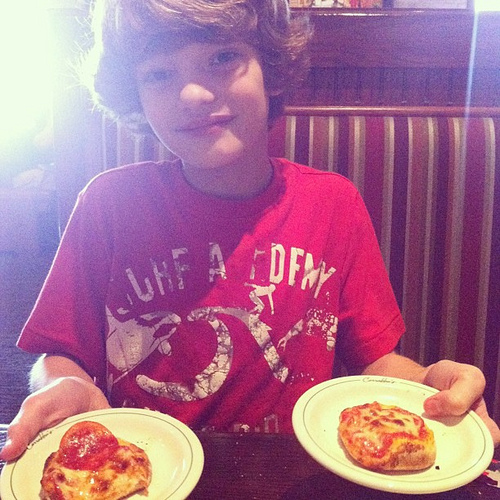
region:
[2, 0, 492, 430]
Young boy holding two saucers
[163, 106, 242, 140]
Mouth of little boy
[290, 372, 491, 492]
White saucer with gold circle near edge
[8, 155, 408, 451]
Red tee shirt with white writing on it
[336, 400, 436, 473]
Sweet roll sitting on white saucer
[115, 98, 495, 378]
Striped colored back of booth back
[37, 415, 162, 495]
Sweet roll with fruit on top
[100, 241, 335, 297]
White writing on red shirt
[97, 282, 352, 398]
White design on front of red shirt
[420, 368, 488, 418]
Left thumb of little boy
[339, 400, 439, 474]
a mini cheese pizza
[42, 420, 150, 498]
a mini pepperoni pizza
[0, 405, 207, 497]
a small white bowl plate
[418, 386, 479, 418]
a boy's thumb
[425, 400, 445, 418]
a boys thumb nail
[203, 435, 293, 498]
a section of brown table with crumbs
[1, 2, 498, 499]
a young boy holding two mini pizzas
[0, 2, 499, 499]
a young boy posing for a picture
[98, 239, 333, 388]
a picture of a shark and a surfer on a wave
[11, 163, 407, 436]
a young boys red shirt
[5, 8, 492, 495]
A kid is holding two plates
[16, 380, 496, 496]
Two plates of pizza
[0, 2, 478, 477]
Boy has on a red shirt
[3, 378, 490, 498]
The plates are plain white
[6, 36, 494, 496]
The boy is sitting in a booth in a food place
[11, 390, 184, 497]
Pepperoni pizza is on one plate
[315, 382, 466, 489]
Cheese pizza is in another plate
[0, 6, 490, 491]
The boy's red shirt has words on it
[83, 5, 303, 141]
A lot of hair on the boy's head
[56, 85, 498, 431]
The seat is striped with different colors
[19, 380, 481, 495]
two plates with pizza on them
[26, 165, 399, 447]
red shirt with white print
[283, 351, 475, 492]
white plate with cheese pizza on it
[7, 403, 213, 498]
white plate with pepperoni pizza on it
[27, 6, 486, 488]
boy holding two slices of pizza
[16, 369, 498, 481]
two white plates with dark colored ring on them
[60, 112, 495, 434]
booth child is sitting in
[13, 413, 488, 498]
table boy is sitting at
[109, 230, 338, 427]
white writing on red shirt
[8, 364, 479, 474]
hands holding white plates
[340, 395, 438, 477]
a mini personal cheese pizza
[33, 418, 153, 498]
a mini personal pepperoni pizza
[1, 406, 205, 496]
a small white shallow bowl with a stripe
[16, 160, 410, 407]
a child's red shirt with a picture of a shark and surfer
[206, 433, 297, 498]
part of a dark wooden table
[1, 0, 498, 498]
a young boy posing for a picture with two mini pizzas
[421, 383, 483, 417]
a young boys thumb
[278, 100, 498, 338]
a stripped booth seat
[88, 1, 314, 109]
a boys brown hair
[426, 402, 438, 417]
thumb nail